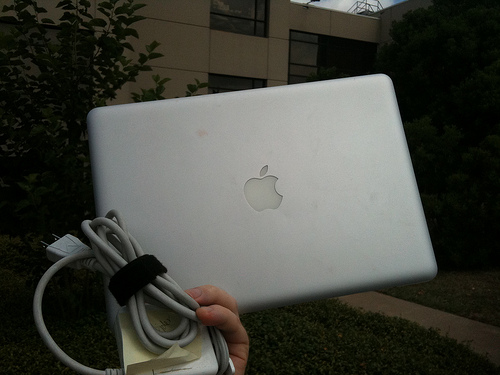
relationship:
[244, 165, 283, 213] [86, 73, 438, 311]
logo on laptop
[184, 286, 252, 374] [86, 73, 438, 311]
hand holding laptop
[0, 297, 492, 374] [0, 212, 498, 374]
grass covering ground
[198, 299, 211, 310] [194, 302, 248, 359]
fingernail on finger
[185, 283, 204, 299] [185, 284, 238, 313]
fingernail on finger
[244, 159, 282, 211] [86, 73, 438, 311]
logo on laptop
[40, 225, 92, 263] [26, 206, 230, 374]
plug on cord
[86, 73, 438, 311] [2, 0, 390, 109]
laptop in front of building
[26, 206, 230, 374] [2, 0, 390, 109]
cord in front of building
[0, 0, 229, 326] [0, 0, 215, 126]
bush has branches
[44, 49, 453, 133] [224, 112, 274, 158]
building with windows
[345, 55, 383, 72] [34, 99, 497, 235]
structure on building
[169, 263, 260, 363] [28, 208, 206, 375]
fingers over wires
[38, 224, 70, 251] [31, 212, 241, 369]
prong in cord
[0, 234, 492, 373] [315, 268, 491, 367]
grass next to ledge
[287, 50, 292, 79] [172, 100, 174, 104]
panes in columns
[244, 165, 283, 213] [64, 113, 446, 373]
logo on laptop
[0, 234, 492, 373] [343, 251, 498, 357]
grass between sidewalk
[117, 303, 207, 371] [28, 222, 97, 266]
note on charger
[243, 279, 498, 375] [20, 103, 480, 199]
bush in front building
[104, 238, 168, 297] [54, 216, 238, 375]
strap holding cord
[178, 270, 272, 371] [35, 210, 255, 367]
fingers around cords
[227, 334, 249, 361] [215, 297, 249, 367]
wrinkles in skin